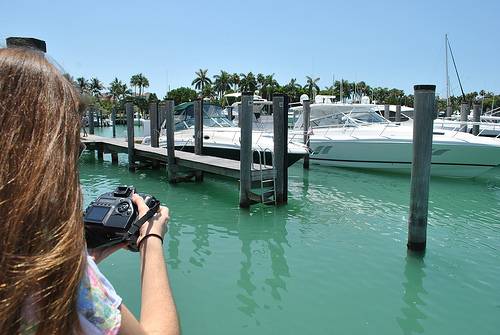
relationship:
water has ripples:
[105, 153, 499, 333] [203, 245, 315, 314]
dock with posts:
[77, 132, 289, 208] [126, 89, 286, 153]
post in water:
[407, 77, 441, 262] [105, 153, 499, 333]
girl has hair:
[0, 37, 182, 335] [2, 48, 79, 277]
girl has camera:
[0, 37, 182, 335] [84, 184, 156, 236]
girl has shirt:
[0, 37, 182, 335] [27, 246, 128, 334]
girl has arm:
[0, 37, 182, 335] [103, 241, 192, 332]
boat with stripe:
[141, 96, 315, 175] [345, 146, 415, 173]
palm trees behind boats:
[128, 72, 151, 97] [130, 97, 308, 182]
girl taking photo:
[3, 31, 189, 333] [3, 3, 492, 321]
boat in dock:
[141, 96, 315, 175] [103, 129, 335, 194]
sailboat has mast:
[400, 29, 498, 139] [442, 31, 472, 118]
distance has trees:
[1, 0, 498, 125] [61, 69, 498, 129]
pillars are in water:
[399, 65, 422, 280] [76, 121, 498, 333]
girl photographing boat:
[0, 37, 182, 335] [141, 96, 315, 175]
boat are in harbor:
[141, 96, 315, 175] [0, 0, 498, 334]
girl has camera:
[0, 37, 182, 335] [72, 181, 167, 251]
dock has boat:
[146, 135, 277, 180] [313, 100, 417, 162]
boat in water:
[264, 94, 499, 179] [68, 164, 499, 332]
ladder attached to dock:
[250, 147, 276, 200] [83, 87, 306, 215]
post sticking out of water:
[407, 83, 436, 251] [76, 121, 498, 333]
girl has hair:
[0, 37, 182, 335] [0, 47, 87, 332]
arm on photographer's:
[120, 179, 187, 334] [0, 37, 184, 334]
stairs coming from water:
[246, 145, 282, 210] [2, 102, 499, 333]